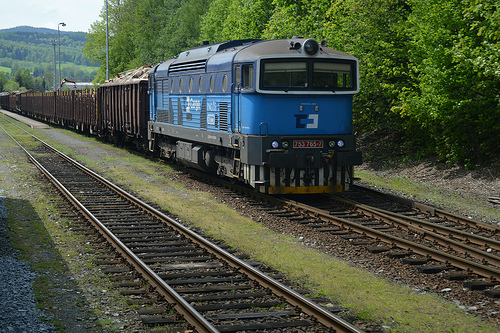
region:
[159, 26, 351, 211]
blue train engine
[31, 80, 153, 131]
brown cargo train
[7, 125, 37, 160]
short yellow and green grass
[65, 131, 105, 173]
short yellow and green grass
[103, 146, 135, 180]
short yellow and green grass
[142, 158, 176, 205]
short yellow and green grass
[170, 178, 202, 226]
short yellow and green grass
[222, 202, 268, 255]
short yellow and green grass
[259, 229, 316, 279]
short yellow and green grass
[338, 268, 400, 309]
short yellow and green grass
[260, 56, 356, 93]
front window of train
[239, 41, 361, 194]
Front head of train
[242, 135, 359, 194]
bottom front of train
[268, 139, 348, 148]
front train head lights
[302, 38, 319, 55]
front train guide light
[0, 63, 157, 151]
Train hauling carge behind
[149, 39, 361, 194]
Front of blue train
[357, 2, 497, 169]
Green bushes growing on side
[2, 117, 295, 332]
A pair of train tracks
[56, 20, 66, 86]
tall lighted lamp post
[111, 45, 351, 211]
train on the track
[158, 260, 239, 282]
brick on the sidewalk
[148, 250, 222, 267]
brick on the sidewalk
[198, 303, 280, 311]
brick on the sidewalk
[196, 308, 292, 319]
brick on the sidewalk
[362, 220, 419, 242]
brick on the sidewalk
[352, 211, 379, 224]
brick on the sidewalk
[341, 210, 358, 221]
brick on the sidewalk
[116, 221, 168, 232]
brick on the sidewalk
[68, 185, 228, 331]
The train tracks on the ground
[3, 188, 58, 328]
The gravel on the ground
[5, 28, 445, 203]
The train on the tracks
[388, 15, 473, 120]
The leaves are short and green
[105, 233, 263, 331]
The tracks are made of metal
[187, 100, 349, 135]
The train is the color blue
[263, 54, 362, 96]
The windshield of the train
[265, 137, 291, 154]
The headlight on the train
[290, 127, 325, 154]
The numbers of the train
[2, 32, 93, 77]
The land is healthy and green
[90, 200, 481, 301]
Track is brown color.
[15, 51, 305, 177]
Train is blue and brown color.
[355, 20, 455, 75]
Trees are green color.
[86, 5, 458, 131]
Trees are in sides of the track.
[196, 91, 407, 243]
Train is in the track.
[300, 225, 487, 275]
Gravel is between the track.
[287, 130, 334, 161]
Numbers are white color.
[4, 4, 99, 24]
Sky is white color.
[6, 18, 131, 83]
Mountain is behind the train.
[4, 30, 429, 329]
Day time picture.